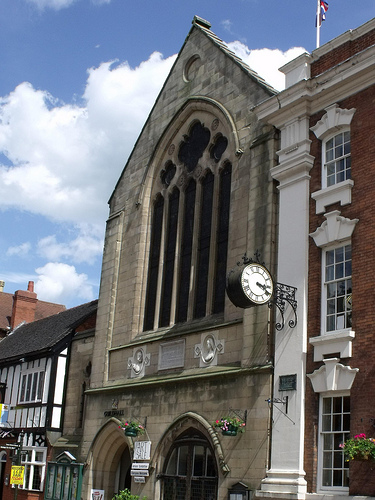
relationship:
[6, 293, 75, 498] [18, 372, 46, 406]
building has windows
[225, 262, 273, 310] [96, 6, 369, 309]
clock on side of building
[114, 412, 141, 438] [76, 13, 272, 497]
flowers hanging on side of building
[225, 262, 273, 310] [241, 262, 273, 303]
clock has face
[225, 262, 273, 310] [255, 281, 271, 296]
clock has hands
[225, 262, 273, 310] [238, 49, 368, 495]
clock attached to building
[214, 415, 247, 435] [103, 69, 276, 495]
plant attached to side of building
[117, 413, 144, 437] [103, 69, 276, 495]
plant attached to side of building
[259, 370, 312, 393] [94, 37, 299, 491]
sign on side of building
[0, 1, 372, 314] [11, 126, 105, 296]
sky has clouds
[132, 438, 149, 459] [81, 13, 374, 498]
sign on front of building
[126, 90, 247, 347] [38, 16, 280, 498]
window on building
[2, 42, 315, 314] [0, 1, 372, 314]
clouds in sky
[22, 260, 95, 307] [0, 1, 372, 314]
cloud in sky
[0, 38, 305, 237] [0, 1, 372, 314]
cloud in sky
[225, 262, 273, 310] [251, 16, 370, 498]
clock on building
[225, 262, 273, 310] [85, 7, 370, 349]
clock extending from building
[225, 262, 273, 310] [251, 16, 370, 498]
clock extending from building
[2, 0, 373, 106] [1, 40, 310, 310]
blue sky with white clouds